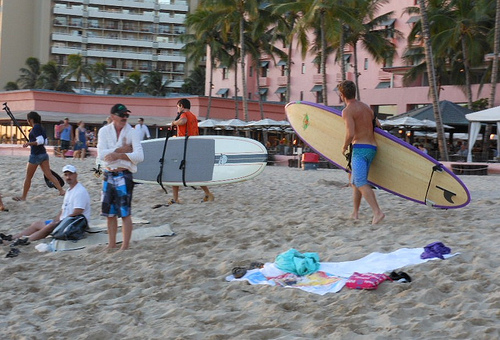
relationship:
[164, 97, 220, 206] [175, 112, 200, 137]
man wearing shirt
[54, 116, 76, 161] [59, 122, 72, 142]
man wearing shirt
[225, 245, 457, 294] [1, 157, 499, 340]
towel on sand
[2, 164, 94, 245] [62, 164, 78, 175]
man wearing hat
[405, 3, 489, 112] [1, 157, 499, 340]
palm tree next to sand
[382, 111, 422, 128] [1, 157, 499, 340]
umbrella next to sand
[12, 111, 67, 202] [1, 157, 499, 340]
girl walking on sand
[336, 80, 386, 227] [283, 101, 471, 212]
man carrying surfboard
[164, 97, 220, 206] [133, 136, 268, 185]
man carrying surfboard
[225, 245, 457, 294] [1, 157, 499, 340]
towel left on sand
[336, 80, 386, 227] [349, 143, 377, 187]
man wearing swim trunks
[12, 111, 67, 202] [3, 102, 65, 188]
girl carrying oars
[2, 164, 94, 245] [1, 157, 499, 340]
man sitting in sand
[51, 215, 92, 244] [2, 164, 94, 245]
backpack next to man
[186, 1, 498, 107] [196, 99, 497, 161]
palm trees next to dining area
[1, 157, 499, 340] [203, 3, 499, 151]
sand next to building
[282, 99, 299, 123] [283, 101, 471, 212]
tip of surfboard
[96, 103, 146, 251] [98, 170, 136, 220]
man wearing shorts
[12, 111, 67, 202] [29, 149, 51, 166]
girl wearing shorts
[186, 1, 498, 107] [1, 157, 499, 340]
palm trees near sand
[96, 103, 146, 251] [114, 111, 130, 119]
man wearing sunglasses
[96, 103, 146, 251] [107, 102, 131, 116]
man wearing hat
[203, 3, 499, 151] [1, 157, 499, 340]
building near sand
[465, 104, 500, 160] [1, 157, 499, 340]
tent near sand